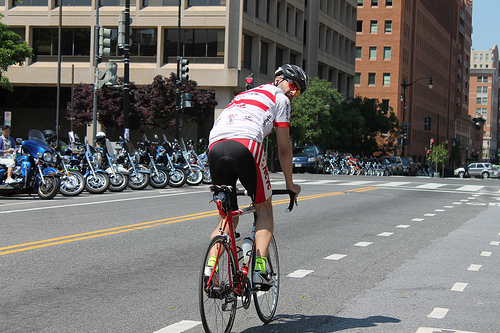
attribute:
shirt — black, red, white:
[212, 83, 289, 139]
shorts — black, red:
[206, 136, 271, 211]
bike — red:
[199, 184, 295, 330]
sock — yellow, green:
[254, 255, 268, 273]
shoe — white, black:
[251, 268, 276, 289]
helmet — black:
[273, 61, 309, 84]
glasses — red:
[287, 81, 303, 97]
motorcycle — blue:
[1, 129, 60, 200]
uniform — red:
[204, 84, 293, 219]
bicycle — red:
[192, 183, 301, 331]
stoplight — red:
[427, 135, 438, 151]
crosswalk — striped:
[215, 171, 498, 194]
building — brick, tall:
[357, 1, 474, 176]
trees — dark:
[67, 74, 216, 142]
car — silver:
[452, 160, 496, 181]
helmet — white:
[93, 130, 108, 143]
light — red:
[242, 71, 252, 91]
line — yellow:
[0, 185, 393, 258]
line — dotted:
[348, 201, 435, 245]